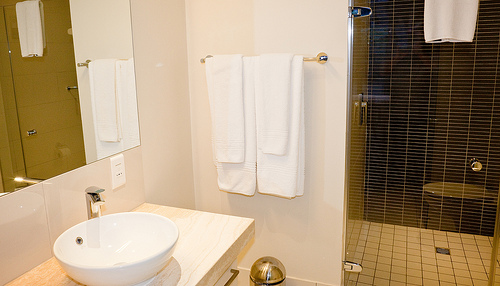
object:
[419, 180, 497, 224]
commode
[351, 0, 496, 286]
barrier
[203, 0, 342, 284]
walls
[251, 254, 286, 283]
can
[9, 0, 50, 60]
towel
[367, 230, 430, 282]
tiles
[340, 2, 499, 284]
door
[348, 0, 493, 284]
stall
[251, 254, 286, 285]
basker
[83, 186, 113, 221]
faucet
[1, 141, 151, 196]
edge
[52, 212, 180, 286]
sink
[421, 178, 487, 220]
seat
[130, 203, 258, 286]
counter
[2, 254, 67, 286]
counter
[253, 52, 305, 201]
towel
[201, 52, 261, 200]
towel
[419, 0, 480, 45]
towel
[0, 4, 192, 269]
wall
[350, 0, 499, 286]
shower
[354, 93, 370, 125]
handle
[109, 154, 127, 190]
outlet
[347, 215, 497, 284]
square tiles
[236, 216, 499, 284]
floor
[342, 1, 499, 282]
glass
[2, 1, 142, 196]
glass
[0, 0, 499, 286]
bathroom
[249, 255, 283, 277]
top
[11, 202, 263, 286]
locker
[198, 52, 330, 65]
rack